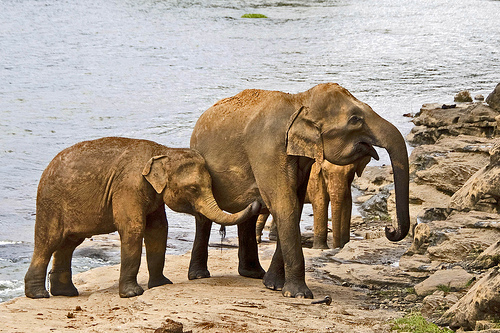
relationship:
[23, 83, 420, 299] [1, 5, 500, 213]
elephants near water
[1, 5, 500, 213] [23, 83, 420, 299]
water near elephants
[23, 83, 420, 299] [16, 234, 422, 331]
elephants on sand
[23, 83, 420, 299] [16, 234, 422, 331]
elephants around sand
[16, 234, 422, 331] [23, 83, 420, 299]
sand around elephants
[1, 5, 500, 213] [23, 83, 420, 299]
water around elephants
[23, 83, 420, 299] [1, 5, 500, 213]
elephants around water